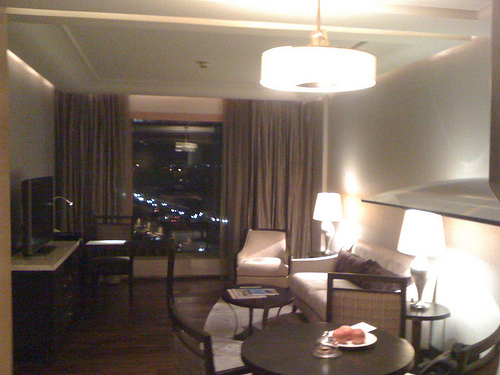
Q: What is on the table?
A: Plates.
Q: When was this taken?
A: During the night.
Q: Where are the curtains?
A: On window.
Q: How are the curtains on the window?
A: Open.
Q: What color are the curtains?
A: Brown.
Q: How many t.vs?
A: One.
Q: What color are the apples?
A: Red.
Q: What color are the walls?
A: White.